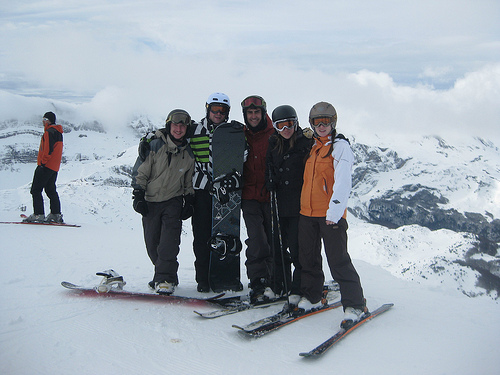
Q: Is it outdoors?
A: Yes, it is outdoors.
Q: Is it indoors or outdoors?
A: It is outdoors.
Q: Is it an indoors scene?
A: No, it is outdoors.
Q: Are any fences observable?
A: No, there are no fences.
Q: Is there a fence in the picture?
A: No, there are no fences.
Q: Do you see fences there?
A: No, there are no fences.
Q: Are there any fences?
A: No, there are no fences.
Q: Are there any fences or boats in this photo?
A: No, there are no fences or boats.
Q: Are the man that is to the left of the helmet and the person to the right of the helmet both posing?
A: Yes, both the man and the person are posing.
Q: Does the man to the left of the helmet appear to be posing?
A: Yes, the man is posing.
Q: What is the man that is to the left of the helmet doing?
A: The man is posing.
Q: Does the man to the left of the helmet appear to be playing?
A: No, the man is posing.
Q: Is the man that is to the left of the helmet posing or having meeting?
A: The man is posing.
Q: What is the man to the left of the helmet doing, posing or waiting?
A: The man is posing.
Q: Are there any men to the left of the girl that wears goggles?
A: Yes, there is a man to the left of the girl.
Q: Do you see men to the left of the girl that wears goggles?
A: Yes, there is a man to the left of the girl.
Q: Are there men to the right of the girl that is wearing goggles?
A: No, the man is to the left of the girl.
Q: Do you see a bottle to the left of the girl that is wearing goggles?
A: No, there is a man to the left of the girl.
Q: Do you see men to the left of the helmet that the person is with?
A: Yes, there is a man to the left of the helmet.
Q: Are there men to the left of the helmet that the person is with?
A: Yes, there is a man to the left of the helmet.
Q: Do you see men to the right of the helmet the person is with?
A: No, the man is to the left of the helmet.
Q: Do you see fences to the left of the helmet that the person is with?
A: No, there is a man to the left of the helmet.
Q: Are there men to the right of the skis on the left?
A: Yes, there is a man to the right of the skis.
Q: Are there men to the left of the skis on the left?
A: No, the man is to the right of the skis.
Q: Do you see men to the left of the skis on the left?
A: No, the man is to the right of the skis.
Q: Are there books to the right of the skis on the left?
A: No, there is a man to the right of the skis.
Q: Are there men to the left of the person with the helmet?
A: Yes, there is a man to the left of the person.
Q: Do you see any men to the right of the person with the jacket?
A: No, the man is to the left of the person.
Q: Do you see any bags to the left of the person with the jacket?
A: No, there is a man to the left of the person.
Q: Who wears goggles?
A: The man wears goggles.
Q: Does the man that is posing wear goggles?
A: Yes, the man wears goggles.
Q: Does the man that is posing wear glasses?
A: No, the man wears goggles.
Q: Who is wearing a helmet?
A: The man is wearing a helmet.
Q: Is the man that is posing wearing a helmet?
A: Yes, the man is wearing a helmet.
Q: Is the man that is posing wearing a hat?
A: No, the man is wearing a helmet.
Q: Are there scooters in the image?
A: No, there are no scooters.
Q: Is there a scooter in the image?
A: No, there are no scooters.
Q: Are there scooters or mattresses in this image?
A: No, there are no scooters or mattresses.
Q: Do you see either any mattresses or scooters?
A: No, there are no scooters or mattresses.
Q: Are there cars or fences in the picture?
A: No, there are no fences or cars.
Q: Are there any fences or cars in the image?
A: No, there are no fences or cars.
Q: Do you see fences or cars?
A: No, there are no fences or cars.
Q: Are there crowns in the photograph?
A: No, there are no crowns.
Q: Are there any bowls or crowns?
A: No, there are no crowns or bowls.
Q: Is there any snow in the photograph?
A: Yes, there is snow.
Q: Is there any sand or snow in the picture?
A: Yes, there is snow.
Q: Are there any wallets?
A: No, there are no wallets.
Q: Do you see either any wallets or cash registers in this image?
A: No, there are no wallets or cash registers.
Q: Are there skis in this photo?
A: Yes, there are skis.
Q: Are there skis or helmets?
A: Yes, there are skis.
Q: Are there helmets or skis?
A: Yes, there are skis.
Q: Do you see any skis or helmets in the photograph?
A: Yes, there are skis.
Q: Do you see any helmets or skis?
A: Yes, there are skis.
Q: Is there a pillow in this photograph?
A: No, there are no pillows.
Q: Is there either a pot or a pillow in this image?
A: No, there are no pillows or pots.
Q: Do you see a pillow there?
A: No, there are no pillows.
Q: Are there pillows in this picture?
A: No, there are no pillows.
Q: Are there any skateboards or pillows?
A: No, there are no pillows or skateboards.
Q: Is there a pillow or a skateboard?
A: No, there are no pillows or skateboards.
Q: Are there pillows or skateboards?
A: No, there are no pillows or skateboards.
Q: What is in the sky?
A: The clouds are in the sky.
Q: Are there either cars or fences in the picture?
A: No, there are no fences or cars.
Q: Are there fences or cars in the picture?
A: No, there are no fences or cars.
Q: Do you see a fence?
A: No, there are no fences.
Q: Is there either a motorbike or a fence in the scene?
A: No, there are no fences or motorcycles.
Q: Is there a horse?
A: No, there are no horses.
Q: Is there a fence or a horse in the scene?
A: No, there are no horses or fences.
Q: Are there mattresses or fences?
A: No, there are no fences or mattresses.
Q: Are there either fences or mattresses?
A: No, there are no fences or mattresses.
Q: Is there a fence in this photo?
A: No, there are no fences.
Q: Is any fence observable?
A: No, there are no fences.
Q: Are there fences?
A: No, there are no fences.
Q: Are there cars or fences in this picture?
A: No, there are no fences or cars.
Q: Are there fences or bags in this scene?
A: No, there are no fences or bags.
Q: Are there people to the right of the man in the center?
A: Yes, there is a person to the right of the man.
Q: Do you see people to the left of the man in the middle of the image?
A: No, the person is to the right of the man.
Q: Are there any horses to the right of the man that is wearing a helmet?
A: No, there is a person to the right of the man.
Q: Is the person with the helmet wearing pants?
A: Yes, the person is wearing pants.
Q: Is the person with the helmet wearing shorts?
A: No, the person is wearing pants.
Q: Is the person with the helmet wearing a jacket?
A: Yes, the person is wearing a jacket.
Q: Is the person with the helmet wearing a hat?
A: No, the person is wearing a jacket.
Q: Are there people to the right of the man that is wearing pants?
A: Yes, there is a person to the right of the man.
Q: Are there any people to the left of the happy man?
A: No, the person is to the right of the man.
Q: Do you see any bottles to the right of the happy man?
A: No, there is a person to the right of the man.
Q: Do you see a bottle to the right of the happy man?
A: No, there is a person to the right of the man.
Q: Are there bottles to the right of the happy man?
A: No, there is a person to the right of the man.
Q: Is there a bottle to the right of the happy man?
A: No, there is a person to the right of the man.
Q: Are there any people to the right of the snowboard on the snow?
A: Yes, there is a person to the right of the snowboard.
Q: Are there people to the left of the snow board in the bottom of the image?
A: No, the person is to the right of the snowboard.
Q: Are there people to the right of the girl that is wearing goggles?
A: Yes, there is a person to the right of the girl.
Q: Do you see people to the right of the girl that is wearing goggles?
A: Yes, there is a person to the right of the girl.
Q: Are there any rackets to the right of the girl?
A: No, there is a person to the right of the girl.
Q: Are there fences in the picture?
A: No, there are no fences.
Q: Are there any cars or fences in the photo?
A: No, there are no fences or cars.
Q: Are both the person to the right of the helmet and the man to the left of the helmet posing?
A: Yes, both the person and the man are posing.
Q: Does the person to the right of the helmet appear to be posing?
A: Yes, the person is posing.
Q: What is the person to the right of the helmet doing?
A: The person is posing.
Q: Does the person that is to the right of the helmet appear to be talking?
A: No, the person is posing.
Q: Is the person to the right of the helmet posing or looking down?
A: The person is posing.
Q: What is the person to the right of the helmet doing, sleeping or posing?
A: The person is posing.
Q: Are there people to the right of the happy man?
A: Yes, there is a person to the right of the man.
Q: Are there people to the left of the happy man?
A: No, the person is to the right of the man.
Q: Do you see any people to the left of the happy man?
A: No, the person is to the right of the man.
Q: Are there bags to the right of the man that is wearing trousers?
A: No, there is a person to the right of the man.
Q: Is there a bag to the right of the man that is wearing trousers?
A: No, there is a person to the right of the man.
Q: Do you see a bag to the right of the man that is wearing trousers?
A: No, there is a person to the right of the man.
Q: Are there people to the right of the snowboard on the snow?
A: Yes, there is a person to the right of the snowboard.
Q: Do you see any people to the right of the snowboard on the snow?
A: Yes, there is a person to the right of the snowboard.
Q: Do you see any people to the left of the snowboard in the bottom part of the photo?
A: No, the person is to the right of the snowboard.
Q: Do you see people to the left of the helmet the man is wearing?
A: No, the person is to the right of the helmet.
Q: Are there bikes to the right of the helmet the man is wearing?
A: No, there is a person to the right of the helmet.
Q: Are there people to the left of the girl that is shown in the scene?
A: Yes, there is a person to the left of the girl.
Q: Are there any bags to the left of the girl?
A: No, there is a person to the left of the girl.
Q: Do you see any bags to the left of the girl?
A: No, there is a person to the left of the girl.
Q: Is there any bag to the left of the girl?
A: No, there is a person to the left of the girl.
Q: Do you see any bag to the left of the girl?
A: No, there is a person to the left of the girl.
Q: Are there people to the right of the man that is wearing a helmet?
A: Yes, there is a person to the right of the man.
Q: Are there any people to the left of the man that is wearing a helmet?
A: No, the person is to the right of the man.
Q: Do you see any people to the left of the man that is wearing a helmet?
A: No, the person is to the right of the man.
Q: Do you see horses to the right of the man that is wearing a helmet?
A: No, there is a person to the right of the man.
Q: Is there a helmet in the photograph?
A: Yes, there is a helmet.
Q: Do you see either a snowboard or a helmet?
A: Yes, there is a helmet.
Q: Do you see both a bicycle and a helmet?
A: No, there is a helmet but no bicycles.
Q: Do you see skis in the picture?
A: Yes, there are skis.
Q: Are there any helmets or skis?
A: Yes, there are skis.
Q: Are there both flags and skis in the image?
A: No, there are skis but no flags.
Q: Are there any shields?
A: No, there are no shields.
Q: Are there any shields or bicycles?
A: No, there are no shields or bicycles.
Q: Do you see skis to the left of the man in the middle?
A: Yes, there are skis to the left of the man.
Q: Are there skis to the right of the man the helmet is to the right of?
A: No, the skis are to the left of the man.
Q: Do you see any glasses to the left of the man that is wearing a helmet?
A: No, there are skis to the left of the man.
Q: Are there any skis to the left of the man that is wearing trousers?
A: Yes, there are skis to the left of the man.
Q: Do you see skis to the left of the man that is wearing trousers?
A: Yes, there are skis to the left of the man.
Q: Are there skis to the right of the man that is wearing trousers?
A: No, the skis are to the left of the man.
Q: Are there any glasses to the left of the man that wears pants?
A: No, there are skis to the left of the man.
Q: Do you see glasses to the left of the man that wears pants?
A: No, there are skis to the left of the man.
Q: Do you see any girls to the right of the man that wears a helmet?
A: Yes, there is a girl to the right of the man.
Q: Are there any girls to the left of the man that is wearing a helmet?
A: No, the girl is to the right of the man.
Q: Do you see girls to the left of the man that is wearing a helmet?
A: No, the girl is to the right of the man.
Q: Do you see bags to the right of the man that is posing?
A: No, there is a girl to the right of the man.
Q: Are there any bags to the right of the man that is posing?
A: No, there is a girl to the right of the man.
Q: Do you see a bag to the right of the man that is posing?
A: No, there is a girl to the right of the man.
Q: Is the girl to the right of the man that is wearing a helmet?
A: Yes, the girl is to the right of the man.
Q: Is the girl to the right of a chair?
A: No, the girl is to the right of the man.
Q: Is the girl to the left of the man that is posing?
A: No, the girl is to the right of the man.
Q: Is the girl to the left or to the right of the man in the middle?
A: The girl is to the right of the man.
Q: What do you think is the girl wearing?
A: The girl is wearing goggles.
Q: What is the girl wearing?
A: The girl is wearing goggles.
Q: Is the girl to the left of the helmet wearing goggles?
A: Yes, the girl is wearing goggles.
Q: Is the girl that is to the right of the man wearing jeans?
A: No, the girl is wearing goggles.